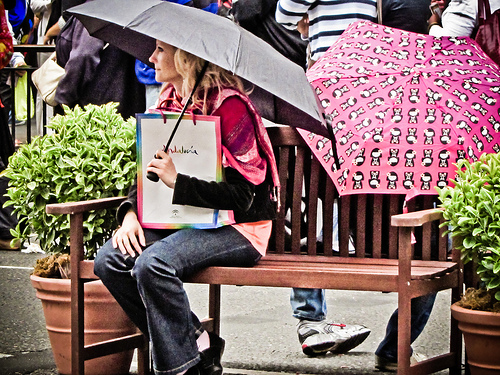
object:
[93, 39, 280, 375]
woman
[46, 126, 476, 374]
bench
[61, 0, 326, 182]
umbrella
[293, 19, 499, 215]
umbrella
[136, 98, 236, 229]
bag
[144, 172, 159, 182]
handle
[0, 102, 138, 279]
plant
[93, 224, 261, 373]
pants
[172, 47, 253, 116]
hair